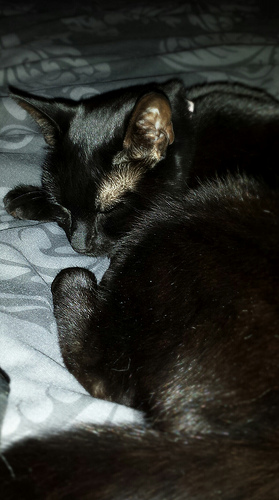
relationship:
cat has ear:
[3, 76, 278, 499] [4, 86, 73, 141]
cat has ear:
[3, 76, 278, 499] [122, 87, 177, 168]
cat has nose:
[3, 76, 278, 499] [72, 243, 94, 257]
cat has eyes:
[3, 76, 278, 499] [45, 193, 127, 222]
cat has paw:
[3, 76, 278, 499] [4, 182, 59, 226]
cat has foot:
[3, 76, 278, 499] [51, 263, 121, 399]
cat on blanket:
[3, 76, 278, 499] [1, 0, 278, 448]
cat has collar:
[3, 76, 278, 499] [172, 93, 200, 129]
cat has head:
[3, 76, 278, 499] [7, 85, 186, 260]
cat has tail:
[3, 76, 278, 499] [0, 423, 279, 499]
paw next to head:
[4, 182, 59, 226] [7, 85, 186, 260]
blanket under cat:
[1, 0, 278, 448] [3, 76, 278, 499]